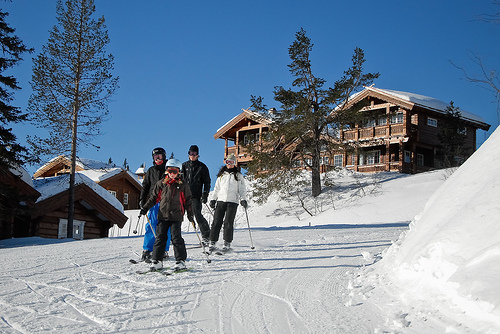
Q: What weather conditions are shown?
A: It is clear.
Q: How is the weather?
A: It is clear.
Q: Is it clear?
A: Yes, it is clear.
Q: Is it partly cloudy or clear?
A: It is clear.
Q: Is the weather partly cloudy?
A: No, it is clear.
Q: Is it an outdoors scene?
A: Yes, it is outdoors.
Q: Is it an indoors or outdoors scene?
A: It is outdoors.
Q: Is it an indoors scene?
A: No, it is outdoors.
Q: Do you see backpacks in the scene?
A: No, there are no backpacks.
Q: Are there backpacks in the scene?
A: No, there are no backpacks.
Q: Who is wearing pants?
A: The skier is wearing pants.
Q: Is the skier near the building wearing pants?
A: Yes, the skier is wearing pants.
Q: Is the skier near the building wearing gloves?
A: No, the skier is wearing pants.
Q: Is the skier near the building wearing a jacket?
A: Yes, the skier is wearing a jacket.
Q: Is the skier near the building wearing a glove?
A: No, the skier is wearing a jacket.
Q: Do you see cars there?
A: No, there are no cars.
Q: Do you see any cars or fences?
A: No, there are no cars or fences.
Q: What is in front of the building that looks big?
A: The tree is in front of the building.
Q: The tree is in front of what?
A: The tree is in front of the building.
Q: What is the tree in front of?
A: The tree is in front of the building.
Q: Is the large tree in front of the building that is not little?
A: Yes, the tree is in front of the building.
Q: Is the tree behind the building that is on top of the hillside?
A: No, the tree is in front of the building.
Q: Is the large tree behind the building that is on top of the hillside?
A: No, the tree is in front of the building.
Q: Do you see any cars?
A: No, there are no cars.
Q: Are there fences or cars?
A: No, there are no cars or fences.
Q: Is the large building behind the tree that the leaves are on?
A: Yes, the building is behind the tree.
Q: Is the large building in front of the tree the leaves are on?
A: No, the building is behind the tree.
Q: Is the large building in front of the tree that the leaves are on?
A: No, the building is behind the tree.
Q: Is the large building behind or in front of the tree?
A: The building is behind the tree.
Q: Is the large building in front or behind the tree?
A: The building is behind the tree.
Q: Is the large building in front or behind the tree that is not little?
A: The building is behind the tree.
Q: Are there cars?
A: No, there are no cars.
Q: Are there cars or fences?
A: No, there are no cars or fences.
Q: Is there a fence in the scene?
A: No, there are no fences.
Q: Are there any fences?
A: No, there are no fences.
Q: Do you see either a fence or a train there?
A: No, there are no fences or trains.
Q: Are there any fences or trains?
A: No, there are no fences or trains.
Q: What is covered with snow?
A: The hillside is covered with snow.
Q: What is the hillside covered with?
A: The hillside is covered with snow.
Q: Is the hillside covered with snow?
A: Yes, the hillside is covered with snow.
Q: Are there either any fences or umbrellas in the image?
A: No, there are no fences or umbrellas.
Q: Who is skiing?
A: The people are skiing.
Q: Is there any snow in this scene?
A: Yes, there is snow.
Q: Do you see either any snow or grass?
A: Yes, there is snow.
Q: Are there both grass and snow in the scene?
A: No, there is snow but no grass.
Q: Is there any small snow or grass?
A: Yes, there is small snow.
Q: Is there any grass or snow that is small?
A: Yes, the snow is small.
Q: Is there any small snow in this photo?
A: Yes, there is small snow.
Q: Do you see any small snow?
A: Yes, there is small snow.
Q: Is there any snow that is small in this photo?
A: Yes, there is small snow.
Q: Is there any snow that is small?
A: Yes, there is snow that is small.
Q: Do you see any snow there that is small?
A: Yes, there is snow that is small.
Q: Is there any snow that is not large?
A: Yes, there is small snow.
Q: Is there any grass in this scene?
A: No, there is no grass.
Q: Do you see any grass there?
A: No, there is no grass.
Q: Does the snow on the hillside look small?
A: Yes, the snow is small.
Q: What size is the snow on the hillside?
A: The snow is small.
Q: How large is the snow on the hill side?
A: The snow is small.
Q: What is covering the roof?
A: The snow is covering the roof.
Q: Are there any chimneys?
A: No, there are no chimneys.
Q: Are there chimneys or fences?
A: No, there are no chimneys or fences.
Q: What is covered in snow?
A: The roof is covered in snow.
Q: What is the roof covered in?
A: The roof is covered in snow.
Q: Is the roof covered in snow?
A: Yes, the roof is covered in snow.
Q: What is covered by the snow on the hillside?
A: The roof is covered by the snow.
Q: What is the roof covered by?
A: The roof is covered by the snow.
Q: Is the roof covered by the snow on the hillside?
A: Yes, the roof is covered by the snow.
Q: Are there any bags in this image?
A: No, there are no bags.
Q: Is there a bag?
A: No, there are no bags.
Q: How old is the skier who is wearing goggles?
A: The skier is young.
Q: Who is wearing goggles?
A: The skier is wearing goggles.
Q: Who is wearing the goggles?
A: The skier is wearing goggles.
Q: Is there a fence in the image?
A: No, there are no fences.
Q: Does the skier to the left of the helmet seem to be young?
A: Yes, the skier is young.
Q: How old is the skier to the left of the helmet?
A: The skier is young.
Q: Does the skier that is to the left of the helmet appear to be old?
A: No, the skier is young.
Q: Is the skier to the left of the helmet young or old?
A: The skier is young.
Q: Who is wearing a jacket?
A: The skier is wearing a jacket.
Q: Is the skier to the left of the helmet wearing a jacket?
A: Yes, the skier is wearing a jacket.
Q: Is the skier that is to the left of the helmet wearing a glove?
A: No, the skier is wearing a jacket.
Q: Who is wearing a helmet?
A: The skier is wearing a helmet.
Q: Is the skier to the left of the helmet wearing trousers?
A: Yes, the skier is wearing trousers.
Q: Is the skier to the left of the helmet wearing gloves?
A: No, the skier is wearing trousers.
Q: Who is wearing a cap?
A: The skier is wearing a cap.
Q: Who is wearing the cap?
A: The skier is wearing a cap.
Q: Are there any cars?
A: No, there are no cars.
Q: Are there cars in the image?
A: No, there are no cars.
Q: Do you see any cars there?
A: No, there are no cars.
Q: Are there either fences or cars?
A: No, there are no cars or fences.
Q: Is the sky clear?
A: Yes, the sky is clear.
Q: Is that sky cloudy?
A: No, the sky is clear.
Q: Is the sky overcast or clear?
A: The sky is clear.